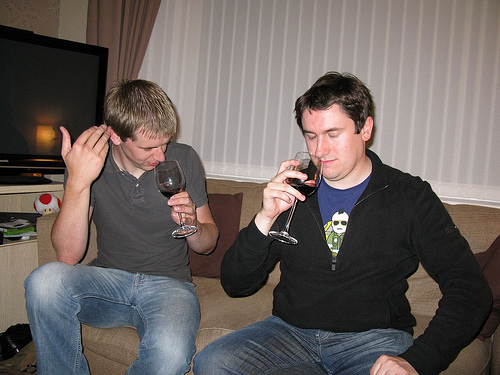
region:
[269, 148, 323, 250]
the wine glass in the mans hand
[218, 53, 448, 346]
the man smelling the wine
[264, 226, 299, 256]
the base of the wine glass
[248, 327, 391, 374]
creases in the pants leg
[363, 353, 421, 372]
the hand on the knee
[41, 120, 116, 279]
the mans hand in the air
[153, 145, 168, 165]
the nose in the cup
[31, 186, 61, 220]
the head of the mushroom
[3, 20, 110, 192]
the black big screen tv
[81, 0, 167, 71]
the brown curtain drape over the window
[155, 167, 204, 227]
man holding a wine glass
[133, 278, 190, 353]
man wearing blue jeans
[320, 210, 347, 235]
drawing on the street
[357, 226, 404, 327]
man is wearing a black sweater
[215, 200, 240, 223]
a pillow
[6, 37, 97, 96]
a television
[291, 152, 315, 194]
a wine glass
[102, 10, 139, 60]
the curtains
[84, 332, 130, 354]
the couch is brown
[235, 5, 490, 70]
the blinds are white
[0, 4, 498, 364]
two men drinking wine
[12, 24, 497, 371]
two men sitting on sofa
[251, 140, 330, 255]
man tilting wine glass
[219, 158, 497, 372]
man wearing black jacket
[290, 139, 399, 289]
man wearing blue shirt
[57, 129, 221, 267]
man wearing grey shirt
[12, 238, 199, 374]
man wearing blue jeans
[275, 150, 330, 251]
red wine in glass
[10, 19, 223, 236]
television monitor next to man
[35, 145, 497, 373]
sofa is light brown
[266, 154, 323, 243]
A glass of a dark beverage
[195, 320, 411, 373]
The man is wearing pants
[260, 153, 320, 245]
A glass in the man's right hand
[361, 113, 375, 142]
The left ear of the man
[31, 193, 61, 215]
A stuffed Toad character near the couch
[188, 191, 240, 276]
A pillow on the couch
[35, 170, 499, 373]
A couch beneath the men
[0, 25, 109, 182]
A television near the men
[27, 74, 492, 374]
Two men sitting on the couch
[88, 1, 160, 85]
A curtain by the window